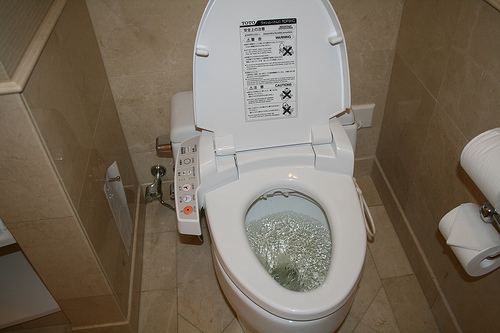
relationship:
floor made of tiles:
[141, 163, 454, 330] [141, 125, 450, 325]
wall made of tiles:
[353, 0, 498, 324] [364, 0, 491, 310]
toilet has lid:
[167, 0, 417, 321] [187, 3, 378, 182]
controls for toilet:
[174, 142, 200, 224] [167, 0, 417, 321]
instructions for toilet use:
[236, 16, 297, 117] [171, 1, 415, 332]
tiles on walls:
[141, 125, 450, 325] [8, 0, 498, 319]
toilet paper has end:
[436, 198, 496, 280] [439, 211, 482, 253]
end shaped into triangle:
[439, 211, 482, 253] [446, 210, 476, 248]